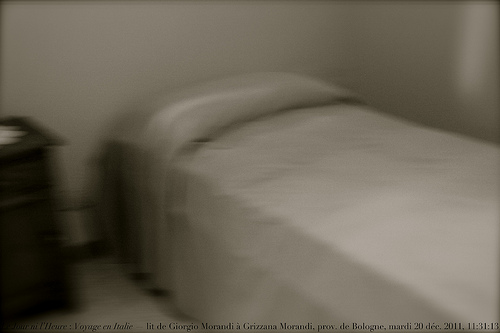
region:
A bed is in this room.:
[95, 27, 499, 312]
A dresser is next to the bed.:
[0, 90, 115, 320]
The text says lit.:
[140, 315, 155, 330]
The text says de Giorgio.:
[155, 315, 197, 330]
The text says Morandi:
[197, 312, 233, 329]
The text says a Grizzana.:
[232, 313, 278, 329]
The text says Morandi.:
[276, 315, 312, 330]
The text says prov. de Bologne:
[315, 317, 385, 330]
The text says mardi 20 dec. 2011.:
[386, 312, 461, 330]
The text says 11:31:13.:
[466, 318, 498, 331]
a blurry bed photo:
[83, 48, 498, 329]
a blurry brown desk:
[3, 93, 104, 320]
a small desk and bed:
[4, 7, 499, 331]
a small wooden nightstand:
[1, 90, 116, 322]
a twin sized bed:
[95, 45, 490, 331]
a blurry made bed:
[76, 38, 499, 323]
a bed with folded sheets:
[79, 47, 499, 329]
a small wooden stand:
[4, 90, 104, 329]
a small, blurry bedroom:
[0, 50, 498, 330]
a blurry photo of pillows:
[91, 40, 393, 193]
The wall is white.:
[7, 1, 492, 144]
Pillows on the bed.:
[137, 52, 349, 153]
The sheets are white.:
[117, 77, 495, 329]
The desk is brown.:
[6, 96, 76, 331]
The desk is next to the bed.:
[0, 104, 75, 325]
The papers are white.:
[0, 115, 32, 150]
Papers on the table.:
[3, 114, 38, 144]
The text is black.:
[19, 324, 495, 331]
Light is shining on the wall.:
[444, 0, 499, 116]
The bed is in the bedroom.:
[72, 44, 498, 331]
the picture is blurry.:
[4, 2, 491, 330]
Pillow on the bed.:
[110, 54, 366, 149]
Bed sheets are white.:
[125, 77, 496, 332]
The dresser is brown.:
[0, 100, 95, 320]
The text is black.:
[15, 317, 496, 330]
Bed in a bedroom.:
[7, 4, 493, 327]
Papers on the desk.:
[0, 117, 30, 149]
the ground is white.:
[64, 252, 197, 331]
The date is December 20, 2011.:
[409, 310, 468, 331]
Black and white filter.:
[3, 4, 498, 331]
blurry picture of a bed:
[65, 37, 486, 322]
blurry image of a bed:
[36, 46, 466, 308]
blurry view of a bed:
[40, 45, 460, 315]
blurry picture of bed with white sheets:
[60, 30, 466, 305]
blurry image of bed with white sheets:
[70, 55, 471, 291]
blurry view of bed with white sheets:
[45, 45, 465, 296]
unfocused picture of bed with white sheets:
[42, 42, 463, 297]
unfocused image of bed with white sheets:
[40, 45, 470, 305]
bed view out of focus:
[69, 43, 463, 307]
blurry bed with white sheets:
[59, 44, 454, 296]